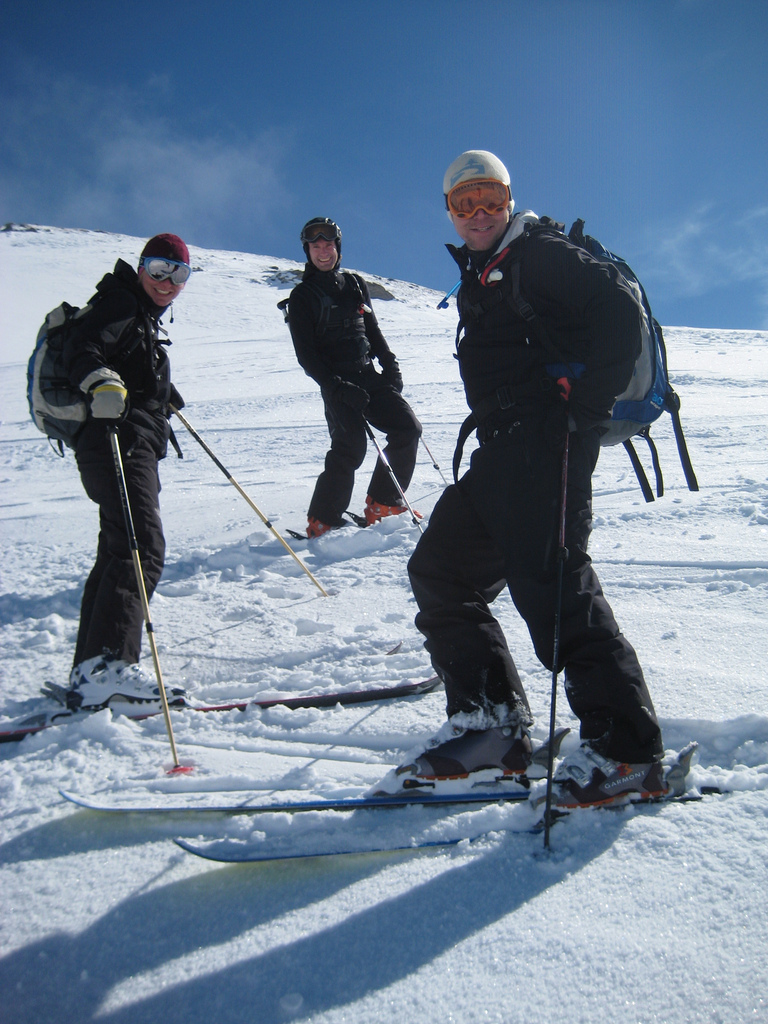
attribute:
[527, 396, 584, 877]
pole — for skiing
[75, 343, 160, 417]
glove — grey, yellow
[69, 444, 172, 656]
ski pants — black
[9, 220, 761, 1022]
snow — white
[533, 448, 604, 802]
pole — skinny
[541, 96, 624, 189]
sky — blue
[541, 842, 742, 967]
snow — white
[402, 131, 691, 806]
person — standing 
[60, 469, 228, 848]
pants — black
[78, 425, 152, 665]
pants — black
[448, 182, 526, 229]
goggles — orange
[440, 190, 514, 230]
goggles — orange